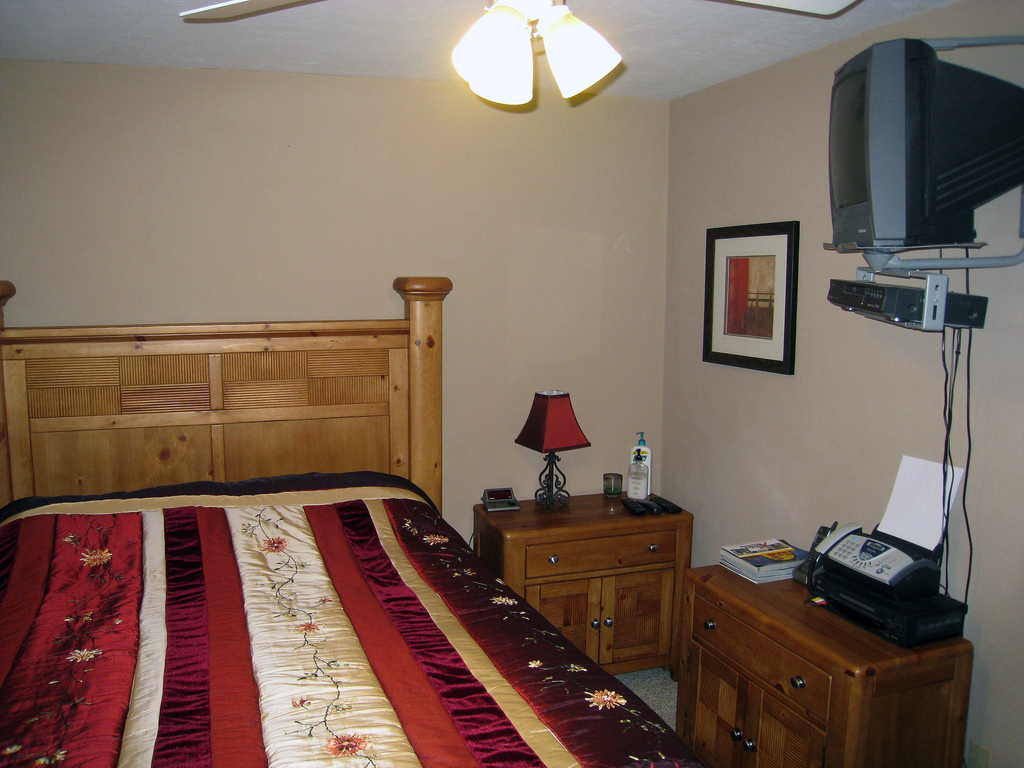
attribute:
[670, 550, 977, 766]
table — brown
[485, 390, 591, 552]
lamp — white, ceiling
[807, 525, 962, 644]
printer — black, white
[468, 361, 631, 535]
lamp — red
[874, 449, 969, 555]
printer paper — white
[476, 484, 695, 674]
brown table — side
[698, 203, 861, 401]
picture — framed